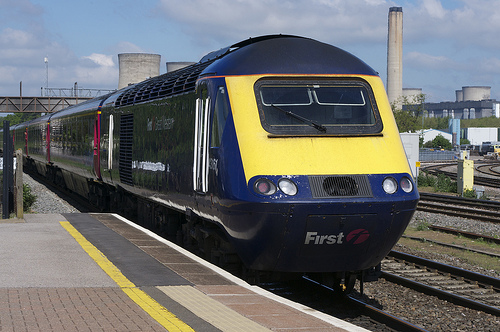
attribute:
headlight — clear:
[380, 178, 395, 194]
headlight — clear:
[278, 178, 298, 196]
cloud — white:
[327, 28, 440, 49]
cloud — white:
[402, 49, 467, 74]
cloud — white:
[150, 0, 485, 44]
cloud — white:
[463, 56, 484, 75]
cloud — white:
[447, 73, 464, 87]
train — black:
[0, 29, 421, 297]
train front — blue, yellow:
[200, 32, 422, 277]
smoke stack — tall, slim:
[385, 4, 404, 111]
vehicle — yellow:
[481, 149, 498, 160]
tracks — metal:
[285, 157, 499, 330]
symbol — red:
[345, 223, 373, 245]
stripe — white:
[113, 209, 365, 330]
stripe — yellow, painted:
[53, 216, 194, 330]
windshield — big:
[254, 73, 379, 134]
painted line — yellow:
[59, 217, 190, 330]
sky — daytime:
[1, 0, 496, 101]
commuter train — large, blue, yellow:
[1, 30, 421, 277]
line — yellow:
[56, 218, 190, 330]